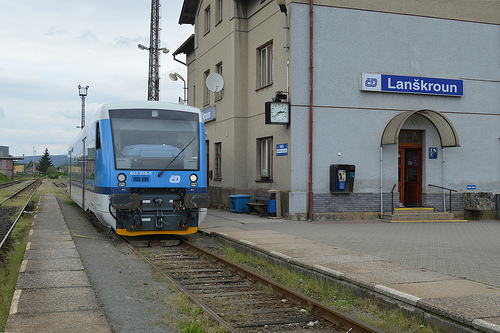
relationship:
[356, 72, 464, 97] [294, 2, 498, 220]
sign on building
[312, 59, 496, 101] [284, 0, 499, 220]
sign on wall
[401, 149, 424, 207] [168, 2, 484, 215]
door with building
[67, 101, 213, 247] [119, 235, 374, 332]
train on a track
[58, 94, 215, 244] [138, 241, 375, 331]
train on track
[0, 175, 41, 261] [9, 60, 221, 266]
track to left of train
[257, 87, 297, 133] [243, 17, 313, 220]
clock on wall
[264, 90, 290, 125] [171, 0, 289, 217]
clock on wall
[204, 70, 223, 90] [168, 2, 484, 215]
satellite dish on building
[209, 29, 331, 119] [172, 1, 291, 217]
window of building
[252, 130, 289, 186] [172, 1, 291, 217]
window of building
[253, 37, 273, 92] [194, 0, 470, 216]
window of building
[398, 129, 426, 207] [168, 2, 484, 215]
door of a building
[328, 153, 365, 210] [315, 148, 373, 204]
payphone with a metal protector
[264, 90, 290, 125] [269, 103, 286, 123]
clock with a face